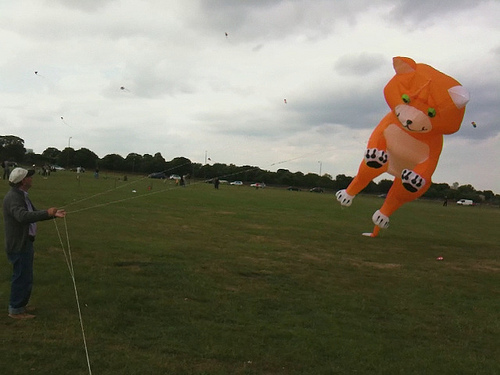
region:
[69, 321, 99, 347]
the string is white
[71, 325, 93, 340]
the string is white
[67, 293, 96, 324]
the string is white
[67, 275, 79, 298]
the string is white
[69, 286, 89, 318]
the string is white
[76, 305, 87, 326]
the string is white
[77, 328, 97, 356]
the string is white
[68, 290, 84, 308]
MAN IS HOLDING STRINGS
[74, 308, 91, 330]
MAN IS HOLDING STRINGS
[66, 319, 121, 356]
MAN IS HOLDING STRINGS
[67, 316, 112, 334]
MAN IS HOLDING STRINGS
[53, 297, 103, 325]
MAN IS HOLDING STRINGS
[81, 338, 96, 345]
MAN IS HOLDING STRINGS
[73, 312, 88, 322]
MAN IS HOLDING STRINGS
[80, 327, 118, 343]
MAN IS HOLDING STRINGS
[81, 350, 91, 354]
MAN IS HOLDING STRINGS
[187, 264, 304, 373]
The grass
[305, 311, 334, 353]
The grass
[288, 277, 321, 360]
The grass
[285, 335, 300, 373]
The grass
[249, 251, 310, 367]
The grass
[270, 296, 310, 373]
The grass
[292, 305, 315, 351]
The grass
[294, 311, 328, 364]
The grass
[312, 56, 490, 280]
The balloon is orange.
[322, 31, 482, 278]
The balloon is large.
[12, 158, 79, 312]
He has a hat on.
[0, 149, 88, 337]
The jacket is brown.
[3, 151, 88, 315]
He is holding rope.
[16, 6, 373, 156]
The sky is overcast and cloudy.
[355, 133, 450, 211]
The paws are black.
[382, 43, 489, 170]
His ear is white.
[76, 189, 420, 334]
The grass is short.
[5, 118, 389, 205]
The trees are in the background.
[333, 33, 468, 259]
large animal ballooon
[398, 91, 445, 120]
two bright green eyes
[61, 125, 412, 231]
two strings attached to the balloon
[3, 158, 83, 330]
man standing on the grass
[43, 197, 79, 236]
hands holding the strings of the balloon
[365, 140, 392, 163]
black claws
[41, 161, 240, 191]
people on the grass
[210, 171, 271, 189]
row of cars parallel parked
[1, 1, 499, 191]
gray sky covered in clouds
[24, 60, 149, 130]
three kites in the sky